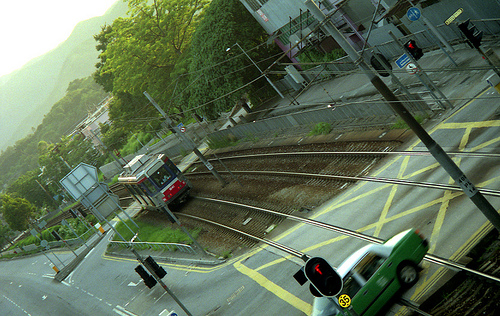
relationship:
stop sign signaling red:
[294, 254, 361, 314] [310, 262, 324, 276]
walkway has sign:
[249, 124, 499, 305] [337, 292, 356, 311]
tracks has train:
[170, 196, 499, 315] [117, 154, 193, 214]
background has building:
[51, 108, 127, 165] [76, 89, 124, 159]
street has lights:
[335, 42, 499, 125] [403, 17, 492, 81]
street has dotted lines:
[14, 235, 147, 315] [59, 269, 115, 308]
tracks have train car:
[186, 189, 346, 268] [117, 154, 193, 214]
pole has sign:
[420, 19, 463, 73] [404, 6, 424, 22]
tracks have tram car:
[186, 189, 346, 268] [117, 154, 193, 214]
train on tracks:
[117, 154, 193, 214] [186, 189, 346, 268]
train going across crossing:
[117, 154, 193, 214] [249, 124, 499, 305]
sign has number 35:
[337, 292, 356, 311] [338, 292, 351, 306]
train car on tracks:
[117, 154, 193, 214] [186, 189, 346, 268]